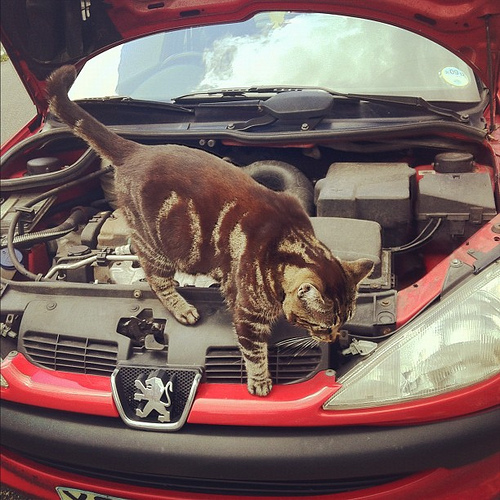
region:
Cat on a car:
[101, 136, 357, 360]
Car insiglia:
[112, 358, 204, 430]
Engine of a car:
[52, 185, 140, 284]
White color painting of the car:
[7, 362, 114, 417]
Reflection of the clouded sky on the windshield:
[191, 32, 401, 89]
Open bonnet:
[0, 6, 136, 96]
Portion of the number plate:
[50, 482, 143, 499]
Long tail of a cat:
[40, 65, 137, 170]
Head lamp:
[360, 295, 480, 410]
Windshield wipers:
[78, 84, 468, 122]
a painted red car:
[3, 3, 498, 489]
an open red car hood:
[0, 4, 495, 111]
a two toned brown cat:
[41, 61, 366, 403]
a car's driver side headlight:
[321, 271, 497, 411]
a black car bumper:
[0, 395, 498, 490]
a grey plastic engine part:
[313, 161, 415, 226]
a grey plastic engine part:
[411, 153, 498, 250]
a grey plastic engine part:
[312, 212, 389, 280]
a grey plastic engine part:
[244, 155, 311, 205]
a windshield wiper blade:
[177, 84, 455, 118]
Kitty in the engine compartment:
[18, 53, 402, 468]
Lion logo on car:
[24, 311, 281, 459]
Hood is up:
[3, 6, 499, 413]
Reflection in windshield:
[153, 35, 474, 98]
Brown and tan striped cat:
[38, 60, 383, 417]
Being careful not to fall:
[31, 60, 394, 406]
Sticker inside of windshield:
[345, 41, 489, 111]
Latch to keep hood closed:
[91, 290, 198, 380]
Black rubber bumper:
[2, 358, 499, 489]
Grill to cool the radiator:
[3, 306, 388, 498]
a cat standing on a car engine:
[3, 4, 499, 472]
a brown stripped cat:
[48, 62, 376, 392]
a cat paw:
[233, 360, 282, 408]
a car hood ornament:
[105, 351, 217, 442]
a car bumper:
[8, 385, 493, 474]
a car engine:
[11, 115, 488, 414]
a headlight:
[333, 285, 492, 454]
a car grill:
[12, 315, 360, 414]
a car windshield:
[68, 19, 493, 119]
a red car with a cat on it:
[1, 3, 489, 498]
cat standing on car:
[42, 62, 359, 393]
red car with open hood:
[6, 75, 83, 473]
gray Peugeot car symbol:
[109, 368, 209, 440]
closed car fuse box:
[414, 170, 494, 250]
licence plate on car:
[46, 480, 136, 497]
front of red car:
[13, 396, 488, 495]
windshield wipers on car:
[93, 86, 477, 124]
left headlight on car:
[376, 274, 498, 399]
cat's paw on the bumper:
[208, 370, 331, 429]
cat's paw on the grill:
[39, 283, 229, 383]